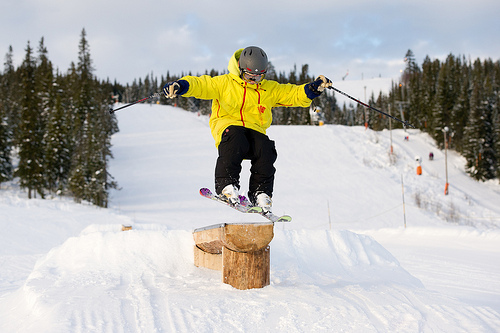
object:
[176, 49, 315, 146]
coat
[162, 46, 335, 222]
skier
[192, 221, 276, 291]
bench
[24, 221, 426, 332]
hill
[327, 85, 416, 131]
ski pole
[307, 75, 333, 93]
hand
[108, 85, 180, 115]
ski pole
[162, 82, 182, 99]
hand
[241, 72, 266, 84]
goggles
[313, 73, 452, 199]
ski lift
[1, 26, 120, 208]
pine tree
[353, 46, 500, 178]
pine tree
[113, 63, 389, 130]
pine tree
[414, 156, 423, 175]
object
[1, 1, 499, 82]
sky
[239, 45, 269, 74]
helmet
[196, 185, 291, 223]
skis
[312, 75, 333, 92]
glove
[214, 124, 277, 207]
pants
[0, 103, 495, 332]
snow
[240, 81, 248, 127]
line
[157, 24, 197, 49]
clouds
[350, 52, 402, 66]
clouds